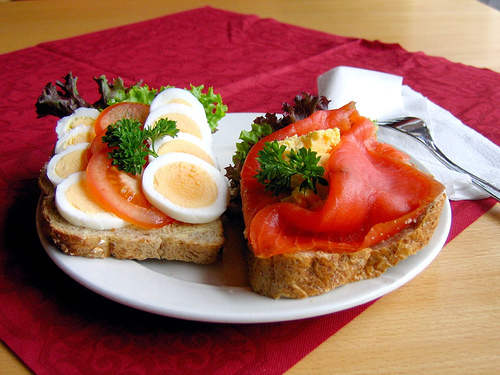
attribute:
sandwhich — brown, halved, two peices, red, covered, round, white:
[54, 87, 216, 250]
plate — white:
[68, 69, 441, 321]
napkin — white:
[334, 66, 486, 168]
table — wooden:
[17, 9, 37, 24]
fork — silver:
[398, 121, 479, 182]